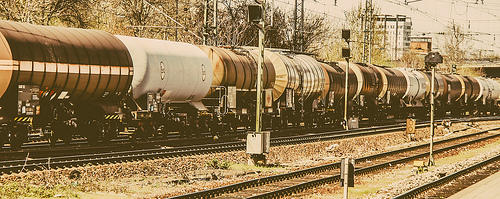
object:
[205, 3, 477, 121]
electric signals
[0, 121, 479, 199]
grass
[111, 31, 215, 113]
tank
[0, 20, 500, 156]
car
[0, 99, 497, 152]
wheels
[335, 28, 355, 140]
electric poll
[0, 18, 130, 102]
tank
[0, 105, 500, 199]
tracks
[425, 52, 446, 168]
light poles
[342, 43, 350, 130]
light poles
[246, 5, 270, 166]
light poles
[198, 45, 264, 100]
tank